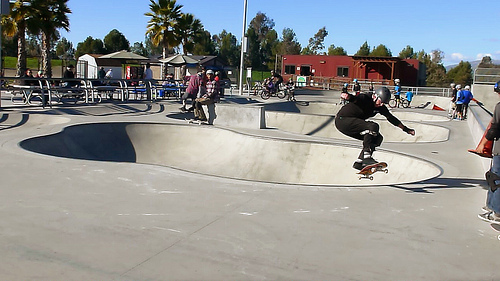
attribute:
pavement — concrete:
[25, 171, 479, 279]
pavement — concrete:
[417, 106, 465, 187]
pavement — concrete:
[8, 109, 124, 126]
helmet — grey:
[372, 83, 392, 103]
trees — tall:
[107, 8, 329, 88]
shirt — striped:
[199, 70, 221, 98]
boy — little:
[403, 85, 414, 105]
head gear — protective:
[373, 83, 391, 105]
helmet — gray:
[372, 87, 394, 104]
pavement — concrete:
[118, 221, 135, 267]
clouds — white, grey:
[386, 20, 457, 71]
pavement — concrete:
[265, 220, 309, 272]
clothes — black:
[337, 87, 411, 156]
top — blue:
[454, 84, 467, 105]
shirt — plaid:
[179, 72, 202, 92]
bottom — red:
[366, 160, 386, 173]